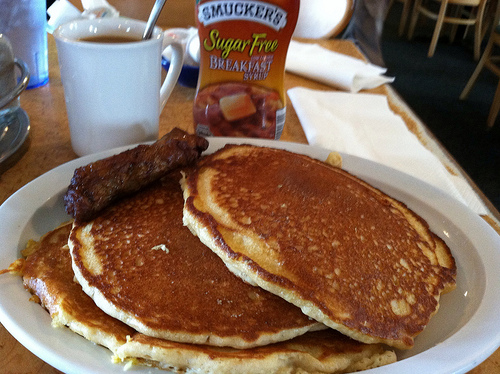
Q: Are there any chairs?
A: Yes, there is a chair.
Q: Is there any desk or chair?
A: Yes, there is a chair.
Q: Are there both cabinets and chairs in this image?
A: No, there is a chair but no cabinets.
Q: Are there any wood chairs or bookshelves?
A: Yes, there is a wood chair.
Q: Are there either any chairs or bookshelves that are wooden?
A: Yes, the chair is wooden.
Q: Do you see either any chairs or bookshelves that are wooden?
A: Yes, the chair is wooden.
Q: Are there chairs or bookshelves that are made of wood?
A: Yes, the chair is made of wood.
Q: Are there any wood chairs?
A: Yes, there is a wood chair.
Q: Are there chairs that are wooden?
A: Yes, there is a chair that is wooden.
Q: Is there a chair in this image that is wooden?
A: Yes, there is a chair that is wooden.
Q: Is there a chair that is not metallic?
A: Yes, there is a wooden chair.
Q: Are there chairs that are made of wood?
A: Yes, there is a chair that is made of wood.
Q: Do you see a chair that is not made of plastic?
A: Yes, there is a chair that is made of wood.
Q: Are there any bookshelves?
A: No, there are no bookshelves.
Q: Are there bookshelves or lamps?
A: No, there are no bookshelves or lamps.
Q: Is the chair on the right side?
A: Yes, the chair is on the right of the image.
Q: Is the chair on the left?
A: No, the chair is on the right of the image.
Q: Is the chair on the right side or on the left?
A: The chair is on the right of the image.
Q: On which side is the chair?
A: The chair is on the right of the image.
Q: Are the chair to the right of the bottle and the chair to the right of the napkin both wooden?
A: Yes, both the chair and the chair are wooden.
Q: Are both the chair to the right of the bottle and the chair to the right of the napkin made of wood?
A: Yes, both the chair and the chair are made of wood.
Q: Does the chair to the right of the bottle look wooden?
A: Yes, the chair is wooden.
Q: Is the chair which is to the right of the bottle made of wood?
A: Yes, the chair is made of wood.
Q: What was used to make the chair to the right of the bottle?
A: The chair is made of wood.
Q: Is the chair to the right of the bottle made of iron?
A: No, the chair is made of wood.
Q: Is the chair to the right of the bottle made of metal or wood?
A: The chair is made of wood.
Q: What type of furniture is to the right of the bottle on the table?
A: The piece of furniture is a chair.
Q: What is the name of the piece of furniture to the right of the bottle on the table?
A: The piece of furniture is a chair.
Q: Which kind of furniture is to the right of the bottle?
A: The piece of furniture is a chair.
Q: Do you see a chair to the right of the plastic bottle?
A: Yes, there is a chair to the right of the bottle.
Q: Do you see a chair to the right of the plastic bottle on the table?
A: Yes, there is a chair to the right of the bottle.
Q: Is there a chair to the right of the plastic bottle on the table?
A: Yes, there is a chair to the right of the bottle.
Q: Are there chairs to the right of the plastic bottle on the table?
A: Yes, there is a chair to the right of the bottle.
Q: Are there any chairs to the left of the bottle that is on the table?
A: No, the chair is to the right of the bottle.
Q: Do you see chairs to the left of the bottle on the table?
A: No, the chair is to the right of the bottle.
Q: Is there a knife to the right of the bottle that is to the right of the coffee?
A: No, there is a chair to the right of the bottle.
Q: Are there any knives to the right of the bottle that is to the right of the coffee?
A: No, there is a chair to the right of the bottle.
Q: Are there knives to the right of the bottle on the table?
A: No, there is a chair to the right of the bottle.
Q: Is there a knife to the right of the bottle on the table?
A: No, there is a chair to the right of the bottle.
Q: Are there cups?
A: Yes, there is a cup.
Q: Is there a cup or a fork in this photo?
A: Yes, there is a cup.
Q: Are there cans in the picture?
A: No, there are no cans.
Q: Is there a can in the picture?
A: No, there are no cans.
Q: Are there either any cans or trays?
A: No, there are no cans or trays.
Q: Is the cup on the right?
A: No, the cup is on the left of the image.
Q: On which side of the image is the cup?
A: The cup is on the left of the image.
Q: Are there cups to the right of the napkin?
A: No, the cup is to the left of the napkin.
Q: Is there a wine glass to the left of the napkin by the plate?
A: No, there is a cup to the left of the napkin.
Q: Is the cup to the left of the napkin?
A: Yes, the cup is to the left of the napkin.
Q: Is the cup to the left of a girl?
A: No, the cup is to the left of the napkin.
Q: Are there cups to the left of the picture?
A: Yes, there is a cup to the left of the picture.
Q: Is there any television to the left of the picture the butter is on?
A: No, there is a cup to the left of the picture.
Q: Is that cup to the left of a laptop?
A: No, the cup is to the left of the picture.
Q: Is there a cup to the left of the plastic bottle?
A: Yes, there is a cup to the left of the bottle.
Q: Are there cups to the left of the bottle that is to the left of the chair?
A: Yes, there is a cup to the left of the bottle.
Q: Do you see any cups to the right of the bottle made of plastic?
A: No, the cup is to the left of the bottle.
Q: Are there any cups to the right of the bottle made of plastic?
A: No, the cup is to the left of the bottle.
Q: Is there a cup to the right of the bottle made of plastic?
A: No, the cup is to the left of the bottle.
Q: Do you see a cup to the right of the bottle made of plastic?
A: No, the cup is to the left of the bottle.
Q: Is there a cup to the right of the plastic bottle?
A: No, the cup is to the left of the bottle.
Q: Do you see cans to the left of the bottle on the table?
A: No, there is a cup to the left of the bottle.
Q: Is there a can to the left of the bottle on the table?
A: No, there is a cup to the left of the bottle.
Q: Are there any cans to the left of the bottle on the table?
A: No, there is a cup to the left of the bottle.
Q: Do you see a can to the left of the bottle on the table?
A: No, there is a cup to the left of the bottle.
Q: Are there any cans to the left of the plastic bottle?
A: No, there is a cup to the left of the bottle.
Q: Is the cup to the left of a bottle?
A: Yes, the cup is to the left of a bottle.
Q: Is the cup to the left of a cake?
A: No, the cup is to the left of a bottle.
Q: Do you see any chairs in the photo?
A: Yes, there is a chair.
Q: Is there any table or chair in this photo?
A: Yes, there is a chair.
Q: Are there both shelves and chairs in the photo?
A: No, there is a chair but no shelves.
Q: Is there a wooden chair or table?
A: Yes, there is a wood chair.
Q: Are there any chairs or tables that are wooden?
A: Yes, the chair is wooden.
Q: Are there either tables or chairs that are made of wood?
A: Yes, the chair is made of wood.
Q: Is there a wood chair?
A: Yes, there is a chair that is made of wood.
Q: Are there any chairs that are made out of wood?
A: Yes, there is a chair that is made of wood.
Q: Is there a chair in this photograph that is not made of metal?
A: Yes, there is a chair that is made of wood.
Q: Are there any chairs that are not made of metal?
A: Yes, there is a chair that is made of wood.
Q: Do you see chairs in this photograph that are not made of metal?
A: Yes, there is a chair that is made of wood.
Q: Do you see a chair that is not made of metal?
A: Yes, there is a chair that is made of wood.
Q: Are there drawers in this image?
A: No, there are no drawers.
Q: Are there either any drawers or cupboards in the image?
A: No, there are no drawers or cupboards.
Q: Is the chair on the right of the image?
A: Yes, the chair is on the right of the image.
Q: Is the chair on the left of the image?
A: No, the chair is on the right of the image.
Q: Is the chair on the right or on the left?
A: The chair is on the right of the image.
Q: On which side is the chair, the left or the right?
A: The chair is on the right of the image.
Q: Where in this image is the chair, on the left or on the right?
A: The chair is on the right of the image.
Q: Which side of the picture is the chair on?
A: The chair is on the right of the image.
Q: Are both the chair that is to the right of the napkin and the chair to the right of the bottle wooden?
A: Yes, both the chair and the chair are wooden.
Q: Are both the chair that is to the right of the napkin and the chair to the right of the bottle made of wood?
A: Yes, both the chair and the chair are made of wood.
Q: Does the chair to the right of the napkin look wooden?
A: Yes, the chair is wooden.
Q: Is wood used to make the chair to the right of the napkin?
A: Yes, the chair is made of wood.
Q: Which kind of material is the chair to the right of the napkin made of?
A: The chair is made of wood.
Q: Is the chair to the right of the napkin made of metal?
A: No, the chair is made of wood.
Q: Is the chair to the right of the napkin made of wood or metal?
A: The chair is made of wood.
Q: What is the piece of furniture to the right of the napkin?
A: The piece of furniture is a chair.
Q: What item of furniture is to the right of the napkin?
A: The piece of furniture is a chair.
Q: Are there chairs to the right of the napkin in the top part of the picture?
A: Yes, there is a chair to the right of the napkin.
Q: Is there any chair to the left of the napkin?
A: No, the chair is to the right of the napkin.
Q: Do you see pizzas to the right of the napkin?
A: No, there is a chair to the right of the napkin.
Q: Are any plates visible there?
A: Yes, there is a plate.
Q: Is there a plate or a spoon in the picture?
A: Yes, there is a plate.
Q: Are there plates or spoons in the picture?
A: Yes, there is a plate.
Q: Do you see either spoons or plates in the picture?
A: Yes, there is a plate.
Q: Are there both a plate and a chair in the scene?
A: Yes, there are both a plate and a chair.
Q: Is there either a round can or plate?
A: Yes, there is a round plate.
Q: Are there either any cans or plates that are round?
A: Yes, the plate is round.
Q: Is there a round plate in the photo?
A: Yes, there is a round plate.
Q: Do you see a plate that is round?
A: Yes, there is a plate that is round.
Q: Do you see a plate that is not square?
A: Yes, there is a round plate.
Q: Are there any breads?
A: No, there are no breads.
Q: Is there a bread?
A: No, there is no breads.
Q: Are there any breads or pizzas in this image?
A: No, there are no breads or pizzas.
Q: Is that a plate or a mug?
A: That is a plate.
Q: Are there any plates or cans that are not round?
A: No, there is a plate but it is round.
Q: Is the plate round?
A: Yes, the plate is round.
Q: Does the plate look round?
A: Yes, the plate is round.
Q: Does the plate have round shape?
A: Yes, the plate is round.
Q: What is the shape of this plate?
A: The plate is round.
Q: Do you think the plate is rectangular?
A: No, the plate is round.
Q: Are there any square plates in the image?
A: No, there is a plate but it is round.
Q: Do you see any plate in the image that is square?
A: No, there is a plate but it is round.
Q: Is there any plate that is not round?
A: No, there is a plate but it is round.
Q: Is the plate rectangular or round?
A: The plate is round.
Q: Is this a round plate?
A: Yes, this is a round plate.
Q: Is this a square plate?
A: No, this is a round plate.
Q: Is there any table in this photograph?
A: Yes, there is a table.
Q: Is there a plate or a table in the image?
A: Yes, there is a table.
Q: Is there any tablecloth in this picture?
A: No, there are no tablecloths.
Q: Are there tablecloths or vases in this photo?
A: No, there are no tablecloths or vases.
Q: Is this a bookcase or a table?
A: This is a table.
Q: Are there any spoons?
A: Yes, there is a spoon.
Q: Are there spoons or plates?
A: Yes, there is a spoon.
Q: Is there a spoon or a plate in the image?
A: Yes, there is a spoon.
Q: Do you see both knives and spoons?
A: No, there is a spoon but no knives.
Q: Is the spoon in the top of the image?
A: Yes, the spoon is in the top of the image.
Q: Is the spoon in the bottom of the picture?
A: No, the spoon is in the top of the image.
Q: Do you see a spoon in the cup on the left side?
A: Yes, there is a spoon in the cup.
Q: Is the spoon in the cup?
A: Yes, the spoon is in the cup.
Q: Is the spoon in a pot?
A: No, the spoon is in the cup.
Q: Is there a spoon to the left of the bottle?
A: Yes, there is a spoon to the left of the bottle.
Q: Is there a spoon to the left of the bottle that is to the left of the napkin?
A: Yes, there is a spoon to the left of the bottle.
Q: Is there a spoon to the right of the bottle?
A: No, the spoon is to the left of the bottle.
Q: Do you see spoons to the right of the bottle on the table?
A: No, the spoon is to the left of the bottle.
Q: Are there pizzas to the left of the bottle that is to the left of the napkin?
A: No, there is a spoon to the left of the bottle.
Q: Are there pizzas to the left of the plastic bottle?
A: No, there is a spoon to the left of the bottle.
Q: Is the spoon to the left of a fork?
A: No, the spoon is to the left of a bottle.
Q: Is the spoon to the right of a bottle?
A: No, the spoon is to the left of a bottle.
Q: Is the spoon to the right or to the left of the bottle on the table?
A: The spoon is to the left of the bottle.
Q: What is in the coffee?
A: The spoon is in the coffee.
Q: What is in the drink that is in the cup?
A: The spoon is in the coffee.